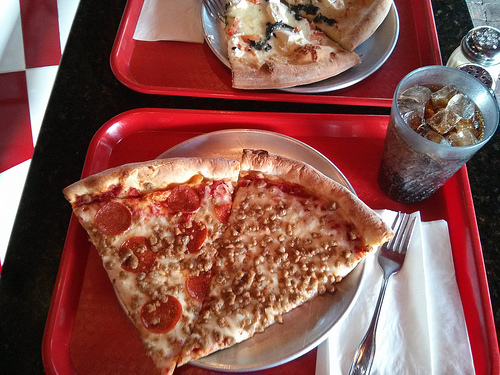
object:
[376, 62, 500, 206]
drink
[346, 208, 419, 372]
fork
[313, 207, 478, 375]
napkin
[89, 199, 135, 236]
pepperoni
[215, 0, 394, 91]
food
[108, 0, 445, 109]
tray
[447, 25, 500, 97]
shakers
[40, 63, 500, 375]
meal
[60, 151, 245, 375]
pizza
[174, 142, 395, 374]
slice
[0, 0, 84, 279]
linoluem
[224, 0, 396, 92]
pizza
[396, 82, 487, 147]
ice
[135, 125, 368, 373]
plate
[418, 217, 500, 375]
part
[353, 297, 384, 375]
part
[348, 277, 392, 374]
handle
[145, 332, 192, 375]
tip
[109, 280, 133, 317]
edge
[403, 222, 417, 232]
part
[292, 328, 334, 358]
edge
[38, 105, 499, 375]
tray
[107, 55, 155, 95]
edge